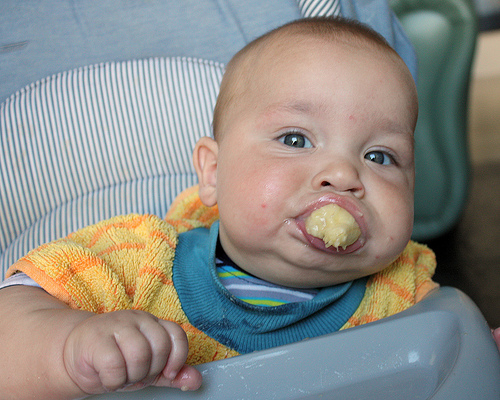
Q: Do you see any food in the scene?
A: Yes, there is food.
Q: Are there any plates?
A: No, there are no plates.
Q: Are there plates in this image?
A: No, there are no plates.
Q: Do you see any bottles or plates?
A: No, there are no plates or bottles.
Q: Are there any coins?
A: No, there are no coins.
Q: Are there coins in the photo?
A: No, there are no coins.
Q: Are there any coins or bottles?
A: No, there are no coins or bottles.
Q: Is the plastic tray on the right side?
A: Yes, the tray is on the right of the image.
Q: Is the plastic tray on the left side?
A: No, the tray is on the right of the image.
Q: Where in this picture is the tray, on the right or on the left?
A: The tray is on the right of the image.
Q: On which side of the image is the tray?
A: The tray is on the right of the image.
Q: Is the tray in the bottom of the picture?
A: Yes, the tray is in the bottom of the image.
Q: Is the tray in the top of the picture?
A: No, the tray is in the bottom of the image.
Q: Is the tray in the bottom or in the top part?
A: The tray is in the bottom of the image.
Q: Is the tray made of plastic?
A: Yes, the tray is made of plastic.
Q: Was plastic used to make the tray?
A: Yes, the tray is made of plastic.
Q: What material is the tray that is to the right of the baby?
A: The tray is made of plastic.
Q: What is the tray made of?
A: The tray is made of plastic.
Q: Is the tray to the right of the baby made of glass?
A: No, the tray is made of plastic.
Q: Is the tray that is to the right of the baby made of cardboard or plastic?
A: The tray is made of plastic.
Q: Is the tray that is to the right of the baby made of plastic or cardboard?
A: The tray is made of plastic.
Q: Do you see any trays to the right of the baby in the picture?
A: Yes, there is a tray to the right of the baby.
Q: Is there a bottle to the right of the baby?
A: No, there is a tray to the right of the baby.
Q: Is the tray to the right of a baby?
A: Yes, the tray is to the right of a baby.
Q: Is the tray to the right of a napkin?
A: No, the tray is to the right of a baby.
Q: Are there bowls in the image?
A: No, there are no bowls.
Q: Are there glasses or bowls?
A: No, there are no bowls or glasses.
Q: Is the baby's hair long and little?
A: No, the hair is little but short.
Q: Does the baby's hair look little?
A: Yes, the hair is little.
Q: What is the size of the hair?
A: The hair is little.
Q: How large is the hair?
A: The hair is little.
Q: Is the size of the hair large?
A: No, the hair is little.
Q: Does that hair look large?
A: No, the hair is little.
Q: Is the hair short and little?
A: Yes, the hair is short and little.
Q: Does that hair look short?
A: Yes, the hair is short.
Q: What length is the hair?
A: The hair is short.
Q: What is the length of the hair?
A: The hair is short.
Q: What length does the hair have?
A: The hair has short length.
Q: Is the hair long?
A: No, the hair is short.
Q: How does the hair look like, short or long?
A: The hair is short.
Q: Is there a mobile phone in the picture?
A: No, there are no cell phones.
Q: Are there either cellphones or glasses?
A: No, there are no cellphones or glasses.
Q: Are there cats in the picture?
A: No, there are no cats.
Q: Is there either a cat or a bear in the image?
A: No, there are no cats or bears.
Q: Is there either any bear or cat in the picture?
A: No, there are no cats or bears.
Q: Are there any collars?
A: Yes, there is a collar.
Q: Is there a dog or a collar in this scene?
A: Yes, there is a collar.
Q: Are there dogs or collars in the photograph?
A: Yes, there is a collar.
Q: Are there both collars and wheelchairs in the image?
A: No, there is a collar but no wheelchairs.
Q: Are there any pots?
A: No, there are no pots.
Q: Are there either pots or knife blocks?
A: No, there are no pots or knife blocks.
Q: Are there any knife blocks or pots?
A: No, there are no pots or knife blocks.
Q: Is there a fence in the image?
A: No, there are no fences.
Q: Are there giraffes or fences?
A: No, there are no fences or giraffes.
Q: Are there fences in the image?
A: No, there are no fences.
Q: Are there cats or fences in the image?
A: No, there are no fences or cats.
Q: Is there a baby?
A: Yes, there is a baby.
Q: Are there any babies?
A: Yes, there is a baby.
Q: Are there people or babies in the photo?
A: Yes, there is a baby.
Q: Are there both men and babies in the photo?
A: No, there is a baby but no men.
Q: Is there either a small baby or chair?
A: Yes, there is a small baby.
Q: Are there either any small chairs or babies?
A: Yes, there is a small baby.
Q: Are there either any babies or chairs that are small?
A: Yes, the baby is small.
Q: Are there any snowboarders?
A: No, there are no snowboarders.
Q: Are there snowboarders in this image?
A: No, there are no snowboarders.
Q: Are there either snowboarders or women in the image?
A: No, there are no snowboarders or women.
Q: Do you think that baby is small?
A: Yes, the baby is small.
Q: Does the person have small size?
A: Yes, the baby is small.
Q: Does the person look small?
A: Yes, the baby is small.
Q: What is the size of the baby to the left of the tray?
A: The baby is small.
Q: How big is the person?
A: The baby is small.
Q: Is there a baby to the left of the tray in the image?
A: Yes, there is a baby to the left of the tray.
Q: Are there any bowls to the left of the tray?
A: No, there is a baby to the left of the tray.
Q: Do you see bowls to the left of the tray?
A: No, there is a baby to the left of the tray.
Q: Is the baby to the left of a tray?
A: Yes, the baby is to the left of a tray.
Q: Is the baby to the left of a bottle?
A: No, the baby is to the left of a tray.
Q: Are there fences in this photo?
A: No, there are no fences.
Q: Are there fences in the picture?
A: No, there are no fences.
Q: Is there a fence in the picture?
A: No, there are no fences.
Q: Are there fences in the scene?
A: No, there are no fences.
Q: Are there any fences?
A: No, there are no fences.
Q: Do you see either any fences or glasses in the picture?
A: No, there are no fences or glasses.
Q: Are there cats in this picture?
A: No, there are no cats.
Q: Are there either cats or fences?
A: No, there are no cats or fences.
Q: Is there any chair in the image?
A: Yes, there is a chair.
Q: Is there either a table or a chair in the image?
A: Yes, there is a chair.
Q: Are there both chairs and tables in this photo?
A: No, there is a chair but no tables.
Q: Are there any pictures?
A: No, there are no pictures.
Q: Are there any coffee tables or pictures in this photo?
A: No, there are no pictures or coffee tables.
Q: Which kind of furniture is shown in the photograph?
A: The furniture is a chair.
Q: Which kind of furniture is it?
A: The piece of furniture is a chair.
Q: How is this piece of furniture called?
A: This is a chair.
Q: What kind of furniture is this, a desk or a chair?
A: This is a chair.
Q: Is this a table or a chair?
A: This is a chair.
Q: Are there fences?
A: No, there are no fences.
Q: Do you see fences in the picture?
A: No, there are no fences.